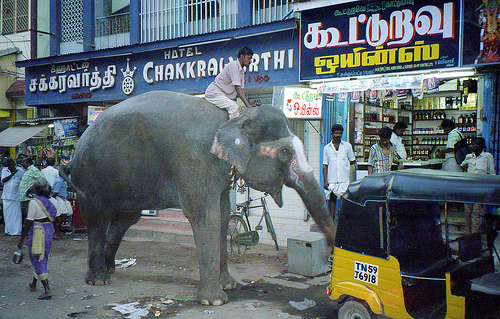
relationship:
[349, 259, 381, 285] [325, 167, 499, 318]
sign on car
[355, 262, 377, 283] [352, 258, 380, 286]
black letters on sign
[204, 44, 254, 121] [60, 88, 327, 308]
man on elephant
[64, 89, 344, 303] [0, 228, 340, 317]
elepahant on road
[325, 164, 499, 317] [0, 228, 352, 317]
car on street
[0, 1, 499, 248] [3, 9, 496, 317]
wall on building